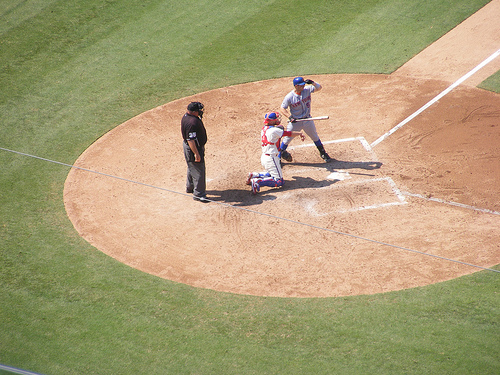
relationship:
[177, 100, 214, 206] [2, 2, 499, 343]
umpire at game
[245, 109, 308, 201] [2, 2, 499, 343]
catcher at game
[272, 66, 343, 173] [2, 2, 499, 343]
batter at game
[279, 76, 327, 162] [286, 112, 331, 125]
player holding bat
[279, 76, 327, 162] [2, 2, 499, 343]
player at game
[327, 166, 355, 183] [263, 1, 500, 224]
plate on diamond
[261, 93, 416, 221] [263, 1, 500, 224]
box on diamond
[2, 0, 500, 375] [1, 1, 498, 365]
grass on field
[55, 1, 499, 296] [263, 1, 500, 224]
dirt on diamond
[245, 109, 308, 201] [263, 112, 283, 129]
catcher has helmet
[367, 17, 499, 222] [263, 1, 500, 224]
baseline on diamond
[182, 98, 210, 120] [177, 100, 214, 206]
helmet on umpire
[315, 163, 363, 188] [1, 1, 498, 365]
base on field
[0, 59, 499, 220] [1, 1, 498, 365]
markings on field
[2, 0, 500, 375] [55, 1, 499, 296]
grass behind dirt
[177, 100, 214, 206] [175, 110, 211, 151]
umpire wearing shirt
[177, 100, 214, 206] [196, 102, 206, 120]
umpire wearing mask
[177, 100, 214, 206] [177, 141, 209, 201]
umpire wearing pants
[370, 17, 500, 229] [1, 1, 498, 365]
lines on field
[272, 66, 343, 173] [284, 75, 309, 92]
batter wearing helmet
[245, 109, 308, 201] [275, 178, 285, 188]
catcher wearing pads